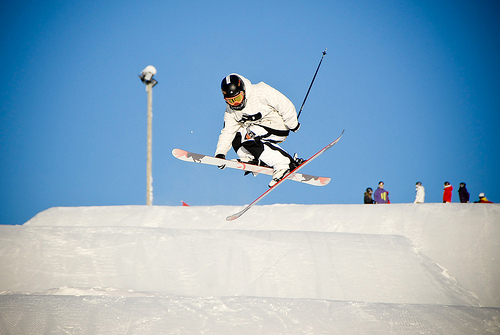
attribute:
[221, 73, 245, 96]
helmet — black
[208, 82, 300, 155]
jacket — white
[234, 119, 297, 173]
pants — black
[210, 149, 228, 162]
glove — black